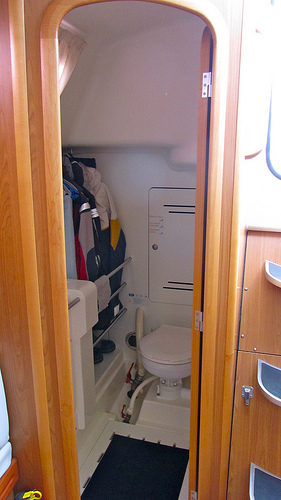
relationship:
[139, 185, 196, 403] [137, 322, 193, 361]
toilet has lid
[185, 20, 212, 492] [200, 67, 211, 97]
door has railing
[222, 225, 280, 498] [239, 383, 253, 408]
door has handle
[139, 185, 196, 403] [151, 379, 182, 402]
toilet has bottom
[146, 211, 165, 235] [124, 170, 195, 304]
label on wall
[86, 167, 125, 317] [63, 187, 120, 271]
clothing has sleeves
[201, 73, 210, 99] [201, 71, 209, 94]
hinge has screws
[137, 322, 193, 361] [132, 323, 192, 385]
lid has toilet bowl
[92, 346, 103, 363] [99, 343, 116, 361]
boot has toes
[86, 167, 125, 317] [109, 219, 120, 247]
clothing has design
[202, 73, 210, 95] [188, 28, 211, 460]
hinge on door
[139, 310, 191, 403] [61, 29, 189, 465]
toilet in bathroom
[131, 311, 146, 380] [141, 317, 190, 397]
pipe beside toilet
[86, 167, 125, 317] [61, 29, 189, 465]
clothing hanging in bathroom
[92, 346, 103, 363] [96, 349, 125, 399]
boot on shelf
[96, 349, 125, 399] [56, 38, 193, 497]
shelf in bathroom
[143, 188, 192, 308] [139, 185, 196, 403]
door behind toilet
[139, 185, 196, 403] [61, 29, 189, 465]
toilet in bathroom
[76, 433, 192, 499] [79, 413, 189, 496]
mat on floor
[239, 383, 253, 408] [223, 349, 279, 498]
handle on door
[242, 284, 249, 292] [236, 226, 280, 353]
button on door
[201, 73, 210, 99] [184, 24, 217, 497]
hinge on door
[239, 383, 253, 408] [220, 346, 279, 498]
handle on cabinet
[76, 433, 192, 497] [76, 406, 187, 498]
mat on floor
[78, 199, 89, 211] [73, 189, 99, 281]
stripes are on clothing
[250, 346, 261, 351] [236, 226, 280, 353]
button on door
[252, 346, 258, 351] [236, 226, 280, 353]
button on door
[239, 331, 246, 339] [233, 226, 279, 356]
button on door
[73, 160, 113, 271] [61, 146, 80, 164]
clothing hanging on rack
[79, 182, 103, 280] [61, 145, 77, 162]
clothing hanging on rack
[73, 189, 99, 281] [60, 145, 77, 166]
clothing hanging on rack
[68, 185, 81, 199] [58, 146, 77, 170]
clothing on rack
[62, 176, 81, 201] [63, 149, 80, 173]
clothing on rack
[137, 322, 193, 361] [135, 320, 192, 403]
lid on toilet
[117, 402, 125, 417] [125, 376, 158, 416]
valve on pipe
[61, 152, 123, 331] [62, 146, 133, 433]
clothes hanging in closet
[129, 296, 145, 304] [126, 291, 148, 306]
lettering printed on sticker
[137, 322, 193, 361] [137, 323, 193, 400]
lid covering toilet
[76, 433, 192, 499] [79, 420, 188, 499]
mat lying on floor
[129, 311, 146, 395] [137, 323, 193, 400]
pipe mounted behind toilet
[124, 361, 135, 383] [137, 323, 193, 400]
valve mounted next to toilet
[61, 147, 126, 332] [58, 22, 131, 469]
clothing hanging in shower area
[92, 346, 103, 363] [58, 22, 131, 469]
boot standing in shower area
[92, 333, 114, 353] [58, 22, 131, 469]
boot standing in shower area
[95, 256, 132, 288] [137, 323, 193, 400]
bar mounted next to toilet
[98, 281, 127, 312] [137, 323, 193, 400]
bar mounted next to toilet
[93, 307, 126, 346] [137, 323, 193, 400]
bar mounted next to toilet